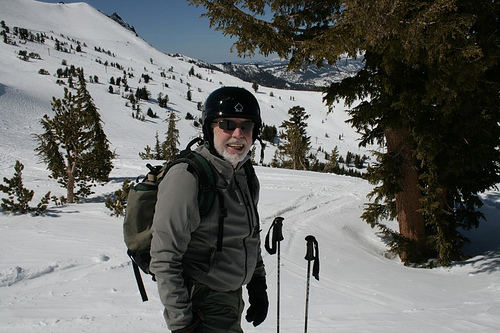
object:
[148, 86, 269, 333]
man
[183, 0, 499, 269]
pine tree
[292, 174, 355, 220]
snow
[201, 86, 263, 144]
helmet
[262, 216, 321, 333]
ski poles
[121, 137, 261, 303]
backpack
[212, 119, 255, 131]
sunglasses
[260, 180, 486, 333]
tracks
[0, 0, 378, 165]
mountain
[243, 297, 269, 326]
glove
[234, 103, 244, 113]
logo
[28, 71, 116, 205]
trees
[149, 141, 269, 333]
jacket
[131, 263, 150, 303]
strap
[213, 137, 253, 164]
beard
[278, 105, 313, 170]
tree